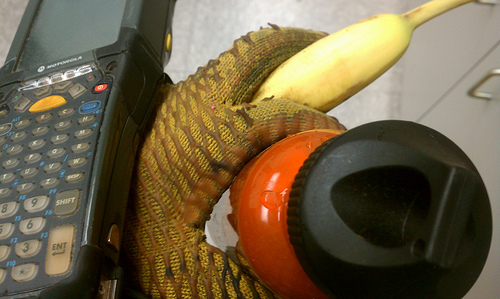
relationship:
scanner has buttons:
[0, 2, 175, 299] [2, 68, 108, 284]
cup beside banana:
[209, 127, 347, 298] [241, 0, 479, 116]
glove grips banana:
[120, 22, 349, 298] [241, 0, 479, 116]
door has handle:
[414, 44, 499, 298] [466, 66, 499, 104]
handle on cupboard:
[466, 66, 499, 104] [400, 2, 497, 298]